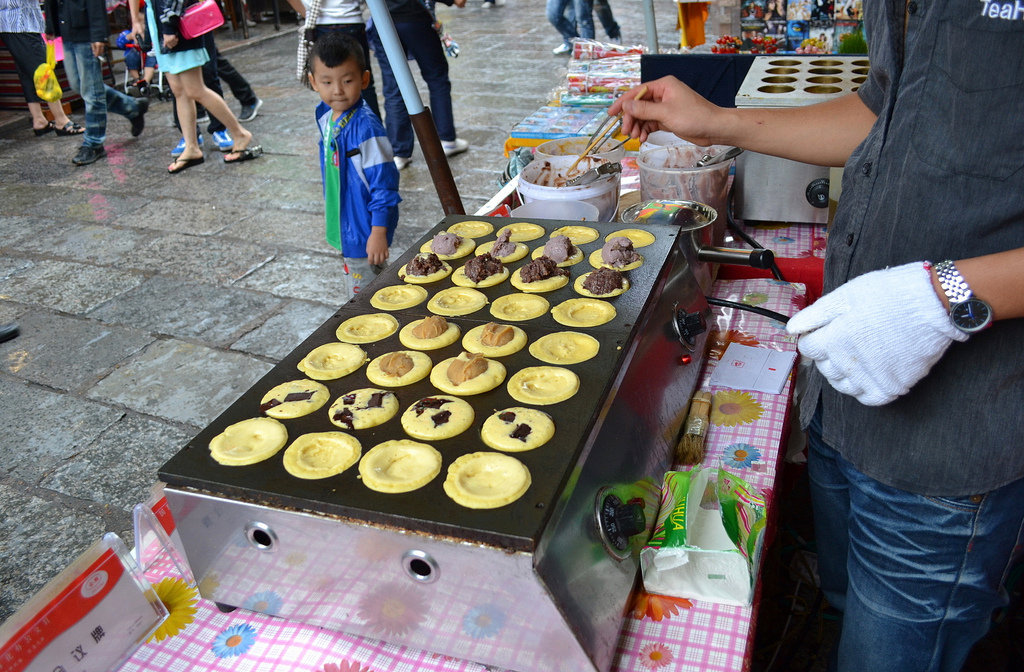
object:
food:
[398, 396, 476, 440]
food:
[297, 341, 370, 381]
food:
[484, 406, 557, 450]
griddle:
[151, 221, 774, 672]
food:
[210, 416, 286, 467]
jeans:
[805, 448, 1024, 672]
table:
[76, 210, 809, 672]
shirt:
[781, 8, 1024, 486]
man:
[609, 0, 1022, 671]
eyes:
[323, 80, 334, 86]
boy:
[305, 29, 412, 287]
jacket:
[304, 99, 402, 259]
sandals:
[169, 152, 205, 173]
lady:
[146, 1, 259, 172]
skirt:
[147, 10, 211, 73]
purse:
[175, 1, 229, 34]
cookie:
[482, 407, 555, 452]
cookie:
[402, 395, 476, 438]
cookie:
[367, 351, 432, 387]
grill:
[164, 214, 684, 547]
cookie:
[512, 256, 565, 292]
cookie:
[442, 451, 532, 509]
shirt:
[321, 108, 400, 254]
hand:
[788, 253, 983, 412]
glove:
[788, 258, 966, 406]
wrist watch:
[922, 259, 993, 332]